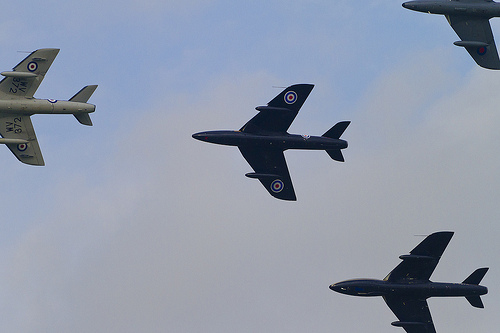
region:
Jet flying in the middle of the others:
[183, 75, 364, 205]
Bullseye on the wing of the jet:
[264, 83, 307, 108]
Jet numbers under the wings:
[7, 76, 28, 137]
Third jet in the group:
[322, 225, 496, 329]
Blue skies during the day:
[115, 2, 242, 70]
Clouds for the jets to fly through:
[73, 218, 263, 331]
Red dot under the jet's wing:
[468, 46, 494, 61]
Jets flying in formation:
[2, 46, 492, 330]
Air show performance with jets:
[1, 43, 496, 332]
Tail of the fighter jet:
[319, 118, 356, 169]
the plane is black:
[186, 86, 361, 189]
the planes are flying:
[7, 43, 395, 316]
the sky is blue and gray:
[122, 97, 171, 254]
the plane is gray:
[0, 49, 130, 191]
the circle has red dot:
[260, 175, 293, 210]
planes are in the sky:
[1, 4, 491, 286]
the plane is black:
[299, 214, 497, 331]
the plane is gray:
[382, 2, 493, 84]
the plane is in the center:
[190, 50, 387, 219]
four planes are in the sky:
[2, 5, 498, 297]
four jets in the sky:
[0, 0, 498, 331]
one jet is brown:
[0, 44, 110, 170]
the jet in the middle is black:
[188, 71, 353, 219]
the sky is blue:
[0, 0, 499, 332]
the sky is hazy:
[3, 1, 498, 331]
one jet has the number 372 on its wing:
[12, 113, 22, 135]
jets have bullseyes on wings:
[16, 43, 490, 195]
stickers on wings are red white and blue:
[263, 76, 298, 193]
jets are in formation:
[1, 0, 496, 331]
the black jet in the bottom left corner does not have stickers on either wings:
[325, 226, 492, 331]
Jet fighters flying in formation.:
[5, 5, 495, 320]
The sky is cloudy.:
[95, 5, 245, 105]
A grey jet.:
[0, 35, 115, 180]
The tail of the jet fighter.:
[295, 120, 360, 175]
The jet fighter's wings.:
[235, 65, 310, 210]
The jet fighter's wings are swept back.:
[180, 75, 360, 210]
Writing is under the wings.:
[0, 70, 30, 140]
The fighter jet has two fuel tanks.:
[320, 210, 490, 325]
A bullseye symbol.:
[270, 80, 315, 105]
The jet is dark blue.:
[180, 70, 361, 218]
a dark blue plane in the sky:
[191, 80, 351, 200]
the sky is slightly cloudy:
[2, 2, 497, 330]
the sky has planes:
[0, 2, 499, 329]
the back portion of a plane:
[1, 45, 100, 170]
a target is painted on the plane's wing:
[280, 87, 300, 107]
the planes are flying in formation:
[2, 1, 497, 331]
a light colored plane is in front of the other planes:
[4, 44, 97, 170]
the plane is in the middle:
[189, 77, 354, 205]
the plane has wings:
[245, 81, 314, 206]